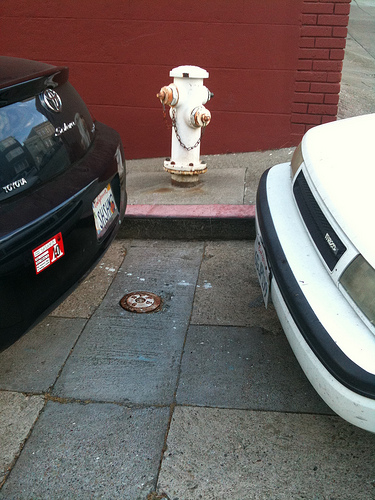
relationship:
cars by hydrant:
[249, 112, 373, 436] [155, 62, 212, 187]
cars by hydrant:
[0, 52, 131, 355] [155, 62, 212, 187]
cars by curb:
[0, 53, 129, 355] [117, 204, 254, 238]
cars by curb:
[251, 112, 375, 436] [117, 204, 254, 238]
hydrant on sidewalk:
[155, 62, 212, 187] [115, 140, 312, 242]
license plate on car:
[82, 190, 122, 233] [0, 33, 139, 349]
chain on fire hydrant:
[162, 107, 202, 151] [155, 62, 216, 177]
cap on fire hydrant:
[157, 84, 165, 102] [155, 62, 216, 177]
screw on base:
[199, 157, 209, 167] [159, 158, 208, 177]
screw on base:
[189, 162, 193, 166] [159, 158, 208, 177]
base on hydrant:
[159, 158, 208, 177] [156, 62, 217, 189]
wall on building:
[1, 1, 349, 160] [0, 1, 351, 161]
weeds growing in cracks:
[18, 383, 176, 498] [0, 238, 373, 497]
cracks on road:
[0, 238, 373, 497] [0, 238, 373, 498]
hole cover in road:
[118, 290, 161, 315] [0, 238, 375, 500]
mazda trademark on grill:
[320, 229, 340, 253] [289, 168, 346, 275]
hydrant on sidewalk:
[155, 64, 214, 189] [103, 136, 355, 242]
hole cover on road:
[114, 285, 163, 316] [0, 238, 373, 498]